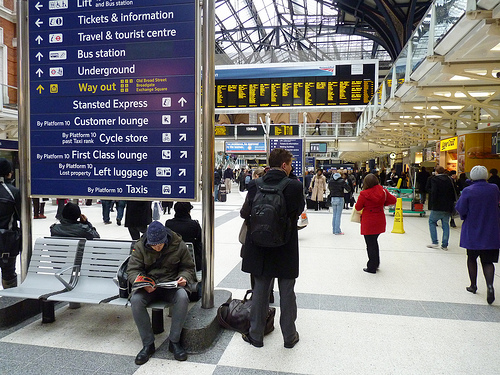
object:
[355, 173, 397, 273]
woman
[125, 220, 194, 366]
person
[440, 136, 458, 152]
sign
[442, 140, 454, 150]
writing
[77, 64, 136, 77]
text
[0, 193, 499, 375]
tile flooring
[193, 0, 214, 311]
metal pole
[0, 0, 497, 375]
train stop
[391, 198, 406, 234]
pylon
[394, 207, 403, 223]
sign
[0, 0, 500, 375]
station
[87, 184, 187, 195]
sign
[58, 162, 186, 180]
sign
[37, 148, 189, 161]
sign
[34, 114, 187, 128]
sign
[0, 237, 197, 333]
bench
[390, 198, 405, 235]
cone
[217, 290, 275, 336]
bag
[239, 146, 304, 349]
person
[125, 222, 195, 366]
man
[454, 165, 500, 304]
woman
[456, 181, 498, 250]
coat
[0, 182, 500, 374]
ground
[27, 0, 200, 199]
blue sign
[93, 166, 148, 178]
white writing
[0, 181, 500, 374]
floor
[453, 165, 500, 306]
person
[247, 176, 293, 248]
backpack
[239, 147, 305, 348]
man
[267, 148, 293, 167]
hair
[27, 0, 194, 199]
sign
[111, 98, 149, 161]
writing